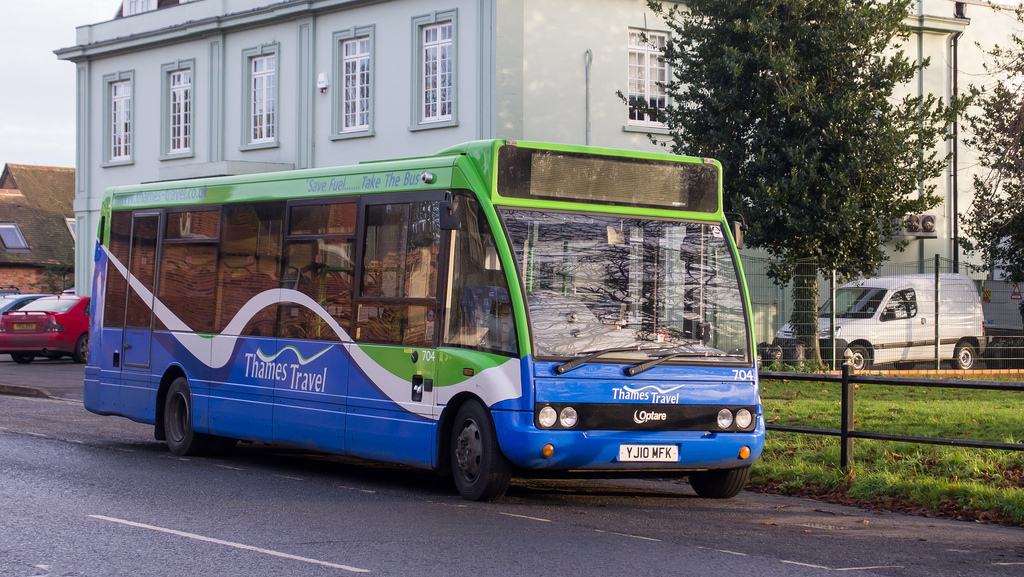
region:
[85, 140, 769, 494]
A blue and green bus on the street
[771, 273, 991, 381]
A parked white van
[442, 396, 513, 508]
A tire on a bus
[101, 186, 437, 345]
Windows on a bus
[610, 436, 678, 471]
A license plate on a bus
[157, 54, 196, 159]
A window on a building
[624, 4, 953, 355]
A tree near a building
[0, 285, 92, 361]
A red car parked near a building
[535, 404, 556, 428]
light on the bus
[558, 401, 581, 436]
light on the bus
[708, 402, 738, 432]
light on the bus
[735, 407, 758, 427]
light on the bus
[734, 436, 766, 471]
light on the bus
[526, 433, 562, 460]
light on the bus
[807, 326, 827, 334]
light on the bus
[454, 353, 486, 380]
light on the bus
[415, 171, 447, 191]
light on the bus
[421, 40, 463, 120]
window on the building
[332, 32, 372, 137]
window on the building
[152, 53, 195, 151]
window on the building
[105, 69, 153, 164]
window on the building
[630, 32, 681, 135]
window on the building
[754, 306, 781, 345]
window on the building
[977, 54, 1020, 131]
window on the building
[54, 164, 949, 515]
blue white and green bus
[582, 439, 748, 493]
black and white license plate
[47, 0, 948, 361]
grey building behind bus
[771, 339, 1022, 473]
black fence near bus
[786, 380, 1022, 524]
green grass behind fence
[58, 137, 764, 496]
Green and blue bus on street.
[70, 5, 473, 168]
Windows on front of building.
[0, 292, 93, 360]
Red car parked by building.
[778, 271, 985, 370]
White van on street next to building.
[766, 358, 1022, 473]
Wooden fence along the grass.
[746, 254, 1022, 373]
Tall wire fence along the side street.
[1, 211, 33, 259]
Window in roof of house.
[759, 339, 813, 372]
Garbage bags next to building.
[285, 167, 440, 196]
Blue lettering on side of bus.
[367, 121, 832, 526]
front of the bus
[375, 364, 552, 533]
front tire of bus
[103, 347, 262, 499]
back tire of bus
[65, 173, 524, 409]
windows on side of bus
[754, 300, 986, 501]
fence next to bus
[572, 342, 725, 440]
words on the bus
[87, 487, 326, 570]
white line on street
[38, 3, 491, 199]
windows on the building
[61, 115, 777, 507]
blue white and green bus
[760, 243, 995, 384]
parked white van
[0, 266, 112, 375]
parked red car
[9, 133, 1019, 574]
bus in a road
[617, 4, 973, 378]
tree with green leaves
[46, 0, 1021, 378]
two story white building with windows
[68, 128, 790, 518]
A Thames Travel bus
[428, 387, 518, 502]
black wheel with black rubber tire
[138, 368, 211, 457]
black wheel with black rubber tire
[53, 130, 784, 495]
number 704 thames travel bus